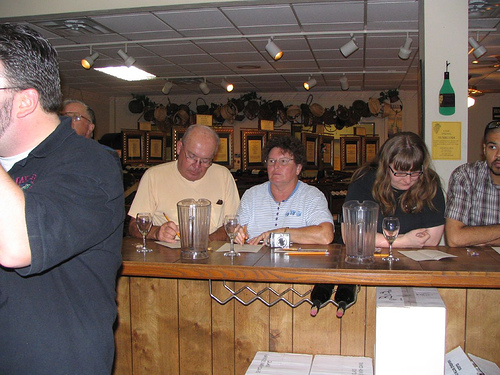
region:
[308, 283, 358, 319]
bottle placed on rack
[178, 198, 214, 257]
glass jug kept in front of man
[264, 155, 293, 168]
woman wearing spectacle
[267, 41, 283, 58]
lights fixed with roof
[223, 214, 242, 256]
wine glasses kept on table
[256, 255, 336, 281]
wooden table top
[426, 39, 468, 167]
white color pillar at background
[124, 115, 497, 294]
Four people sitting at a bar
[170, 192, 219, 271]
A glass pitcher on the bar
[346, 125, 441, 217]
Woman has long brown hair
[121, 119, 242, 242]
Man wearing a yellow shirt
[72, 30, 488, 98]
Lights are on the ceiling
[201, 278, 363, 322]
Two bottles of wine on a rack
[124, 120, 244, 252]
A man is writing on paper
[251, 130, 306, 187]
Woman is wearing glasses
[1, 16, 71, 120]
A man has brown hair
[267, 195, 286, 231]
Buttons are on a shirt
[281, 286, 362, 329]
bottles of wine under the counter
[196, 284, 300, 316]
wine rack under the counter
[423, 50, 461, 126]
bottle of wine drawn on the wall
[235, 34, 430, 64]
track lighting in the ceiling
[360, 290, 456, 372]
white box under the counter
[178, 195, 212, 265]
empty pitcher on the table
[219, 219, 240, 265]
empty glass on the table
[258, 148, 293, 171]
woman is wearing glasses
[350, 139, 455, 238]
woman is leaning over on the bar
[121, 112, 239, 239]
man is writing at the bar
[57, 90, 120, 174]
a person sitting at the bar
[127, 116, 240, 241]
a person sitting at the bar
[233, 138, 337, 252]
a person sitting at the bar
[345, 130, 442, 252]
a person sitting at the bar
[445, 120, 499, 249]
a person sitting at the bar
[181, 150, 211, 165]
a pair of eye glasses on face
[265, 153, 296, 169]
a pair of eye glasses on face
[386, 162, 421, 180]
a pair of eye glasses on face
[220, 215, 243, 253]
a wine glass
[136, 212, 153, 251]
a wine glass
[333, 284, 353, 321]
a bottle of wine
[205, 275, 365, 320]
two wine bottles on wine rack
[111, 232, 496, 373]
wooden bar with an attached wine rack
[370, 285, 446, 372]
a bunch of papers in plastic wrap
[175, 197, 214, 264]
empty plastic pitcher on the bar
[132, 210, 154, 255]
empty wine glass on the bar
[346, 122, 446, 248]
woman in black shirt and glasses reading at the bar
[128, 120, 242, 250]
man in glasses sitting at the bar writing with a pencil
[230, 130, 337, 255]
curly short haired woman sitting at the bar writing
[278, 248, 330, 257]
yellow pencil with eraser tip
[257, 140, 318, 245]
woman using a blue and white shirt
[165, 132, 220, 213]
man weraring yellow shirt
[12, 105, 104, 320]
man wearing a bue shirt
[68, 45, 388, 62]
white ceilin lights in a line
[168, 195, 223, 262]
empty pitcher on counter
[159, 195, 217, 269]
empty pitcher on counter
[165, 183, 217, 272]
empty pitcher on counter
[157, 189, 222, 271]
empty pitcher on counter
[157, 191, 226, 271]
empty pitcher on counter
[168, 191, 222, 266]
empty pitcher on counter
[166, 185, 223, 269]
empty pitcher on counter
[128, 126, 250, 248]
The man in the yellow shirt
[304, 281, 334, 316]
Wine on the rack